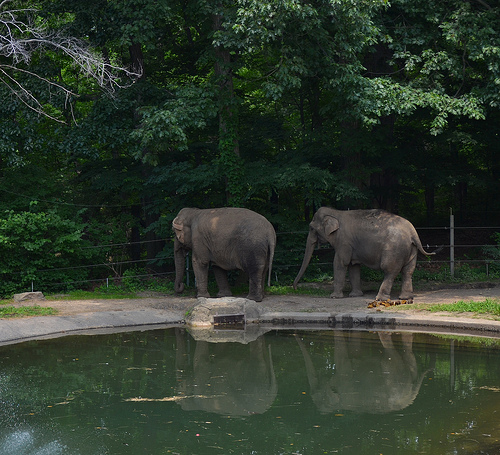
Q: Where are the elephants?
A: In zoo.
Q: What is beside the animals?
A: A pond.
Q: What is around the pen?
A: Fence.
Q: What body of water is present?
A: Pond.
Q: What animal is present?
A: Elephants.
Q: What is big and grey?
A: Elephant.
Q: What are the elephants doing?
A: Standing.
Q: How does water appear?
A: Calm.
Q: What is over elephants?
A: Tree branches.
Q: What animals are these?
A: Elephants.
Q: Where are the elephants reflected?
A: In a man-made, circular pool.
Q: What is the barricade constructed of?
A: Metal.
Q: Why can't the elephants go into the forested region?
A: There is a metal barricade, stopping them.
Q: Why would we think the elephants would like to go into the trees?
A: Because both elephants are standing close to the fence, facing the trees.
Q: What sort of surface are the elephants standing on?
A: A cement walkway.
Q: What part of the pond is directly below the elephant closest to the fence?
A: The pond's drain.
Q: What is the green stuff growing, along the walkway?
A: Grass.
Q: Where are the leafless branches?
A: Far left, near the top .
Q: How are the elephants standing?
A: Their back to the camera.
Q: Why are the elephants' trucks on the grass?
A: They're getting food.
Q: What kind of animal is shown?
A: Elephant.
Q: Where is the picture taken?
A: Zoo.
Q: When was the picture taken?
A: During the daytime.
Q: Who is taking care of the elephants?
A: Zoo worker.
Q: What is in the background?
A: Trees with green leaves.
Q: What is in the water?
A: Reflection of the elephants.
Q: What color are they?
A: Grey.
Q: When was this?
A: Daytime.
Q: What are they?
A: Elephants.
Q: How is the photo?
A: Clear.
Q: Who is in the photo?
A: Nobody.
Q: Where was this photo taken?
A: At a zoo.